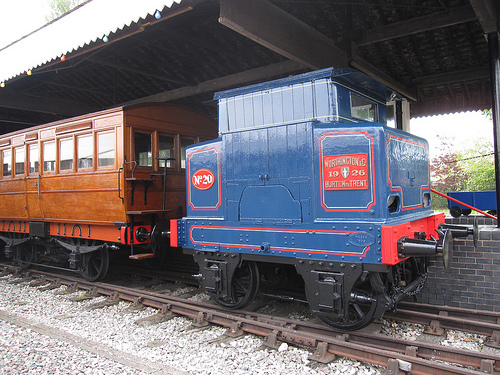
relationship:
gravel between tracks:
[439, 330, 490, 351] [0, 259, 494, 369]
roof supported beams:
[91, 23, 200, 78] [252, 26, 335, 58]